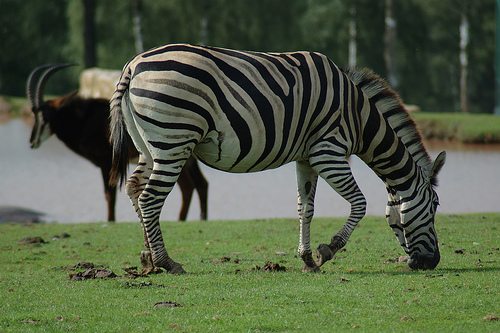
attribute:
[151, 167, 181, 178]
stripe — black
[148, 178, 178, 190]
stripe — black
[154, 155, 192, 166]
stripe — black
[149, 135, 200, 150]
stripe — black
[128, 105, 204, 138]
stripe — black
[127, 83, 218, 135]
stripe — black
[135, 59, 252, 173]
stripe — black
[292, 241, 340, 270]
hoves — grey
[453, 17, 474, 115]
tree — white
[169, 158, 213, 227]
knees — bent backwards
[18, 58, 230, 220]
antelope — sable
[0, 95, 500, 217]
water — brown, dirty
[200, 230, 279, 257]
grass — green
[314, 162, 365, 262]
leg — bent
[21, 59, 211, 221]
antelope — sable, blurry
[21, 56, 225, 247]
ram — dark brown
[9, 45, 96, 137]
horns — curved, dark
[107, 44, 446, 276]
zebra — mammal, white, eating, grazing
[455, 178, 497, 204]
water — full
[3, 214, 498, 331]
grass — green, neat, trimmed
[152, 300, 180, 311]
indent — small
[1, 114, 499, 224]
water — muddy, brown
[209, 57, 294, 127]
stripes — black, white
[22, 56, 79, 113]
horns — curved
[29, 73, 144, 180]
animal — brown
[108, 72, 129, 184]
tail — small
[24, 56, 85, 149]
horns — black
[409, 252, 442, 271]
mouth — black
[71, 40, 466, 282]
zebra — eating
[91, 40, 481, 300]
zebra — dark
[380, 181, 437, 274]
jaw — lower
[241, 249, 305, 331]
grass — green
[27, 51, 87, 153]
antelope — sable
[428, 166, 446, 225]
eyelash — long